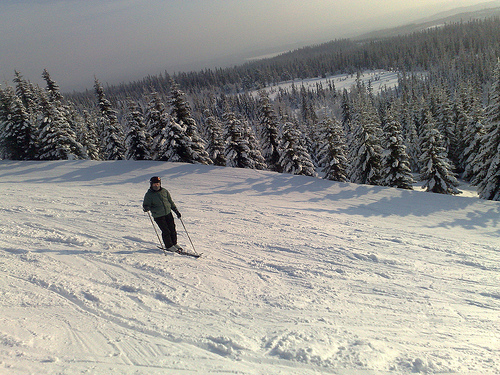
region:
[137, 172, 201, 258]
Athletic skier on slope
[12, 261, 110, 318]
ski tracks in snow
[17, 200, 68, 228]
ski tracks in snow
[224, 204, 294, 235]
Ski tracks in snow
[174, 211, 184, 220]
Hand of skier on slope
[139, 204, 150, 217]
Hand of skier on slope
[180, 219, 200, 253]
Ski pole of athlete on slope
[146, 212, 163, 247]
Ski pole of athlete on slope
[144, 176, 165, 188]
Head of skier on slope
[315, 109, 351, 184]
Snow covered tree on slope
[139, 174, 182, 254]
THIS IS A MAN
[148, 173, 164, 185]
THIS IS HIS HAT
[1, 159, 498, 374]
THIS IS THE SNOW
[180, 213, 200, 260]
THIS IS A STICK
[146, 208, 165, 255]
THIS IS ANOTHER STICK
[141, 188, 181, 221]
THIS IS A GREEN COAT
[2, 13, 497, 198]
THESE ARE GREEN TREES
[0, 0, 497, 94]
THIS IS THE SKY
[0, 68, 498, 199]
THIS IS SNOW ON THE TREES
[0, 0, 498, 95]
THE SKIES ARE CLOUDY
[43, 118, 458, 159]
several trees covered with snow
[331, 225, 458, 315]
tracks in the snow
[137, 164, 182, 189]
a man wearing a helmet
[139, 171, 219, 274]
a man holding ski poles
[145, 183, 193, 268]
a man on snow skis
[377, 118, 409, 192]
a tree covered with snow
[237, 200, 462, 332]
the ground covered in snow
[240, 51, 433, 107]
a cleared field covered with snow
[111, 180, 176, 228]
a man wearing a coat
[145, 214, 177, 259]
a man wearing black pants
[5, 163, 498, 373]
white snow-covered ski slope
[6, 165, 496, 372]
ski slope with many tracks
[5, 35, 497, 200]
snow-covered fir trees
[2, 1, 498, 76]
gray and cloudy sky above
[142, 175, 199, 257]
man skiing down the mountain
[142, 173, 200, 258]
man in a green ski jacket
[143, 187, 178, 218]
dark green ski jacket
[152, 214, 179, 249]
black snow pants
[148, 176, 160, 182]
red ski helmet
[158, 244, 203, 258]
a pair of snow skis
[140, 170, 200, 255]
Man skiing in the snow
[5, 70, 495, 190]
Snow covered pine trees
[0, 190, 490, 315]
Ski tracks in the snow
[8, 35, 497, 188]
Snowy winter landscape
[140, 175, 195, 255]
Man wearing a ski helmet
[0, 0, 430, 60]
Gray winter sky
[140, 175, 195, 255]
Man leaning into turn skiing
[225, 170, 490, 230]
Pine tree shadows over snow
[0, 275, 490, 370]
Powder snow for skiing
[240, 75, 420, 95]
Wintery field amidst pine trees